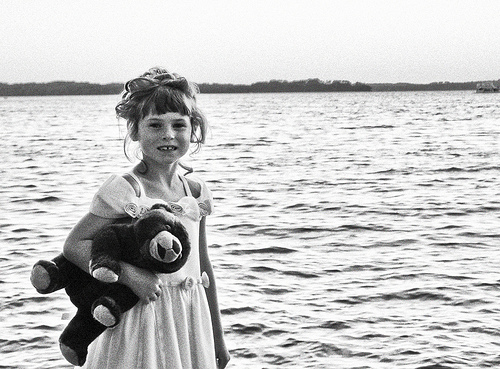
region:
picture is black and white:
[12, 23, 450, 313]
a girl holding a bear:
[16, 77, 244, 364]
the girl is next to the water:
[39, 67, 461, 362]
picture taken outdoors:
[39, 41, 462, 353]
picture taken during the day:
[9, 8, 494, 318]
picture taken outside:
[52, 54, 489, 364]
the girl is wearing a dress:
[77, 176, 224, 364]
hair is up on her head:
[105, 58, 212, 180]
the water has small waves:
[265, 93, 432, 264]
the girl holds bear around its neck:
[97, 174, 227, 357]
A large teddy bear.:
[33, 200, 201, 365]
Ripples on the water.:
[272, 255, 455, 339]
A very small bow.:
[181, 271, 218, 293]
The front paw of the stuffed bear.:
[92, 301, 115, 326]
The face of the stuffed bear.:
[133, 208, 188, 276]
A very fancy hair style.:
[110, 62, 208, 113]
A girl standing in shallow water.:
[103, 58, 233, 368]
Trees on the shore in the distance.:
[9, 75, 107, 97]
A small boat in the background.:
[473, 76, 498, 94]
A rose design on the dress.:
[120, 201, 142, 219]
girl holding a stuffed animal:
[18, 76, 259, 348]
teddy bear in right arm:
[48, 195, 208, 347]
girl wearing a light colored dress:
[114, 175, 224, 362]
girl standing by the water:
[29, 71, 476, 367]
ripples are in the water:
[272, 198, 494, 303]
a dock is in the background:
[466, 73, 498, 101]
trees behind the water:
[217, 75, 405, 105]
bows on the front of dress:
[173, 267, 221, 304]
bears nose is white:
[149, 233, 184, 275]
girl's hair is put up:
[114, 71, 217, 128]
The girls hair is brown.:
[107, 66, 209, 171]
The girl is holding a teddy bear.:
[27, 64, 229, 367]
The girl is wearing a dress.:
[28, 66, 229, 366]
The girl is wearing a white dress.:
[24, 56, 229, 367]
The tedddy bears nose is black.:
[168, 238, 183, 255]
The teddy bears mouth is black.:
[153, 241, 169, 260]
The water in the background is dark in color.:
[277, 148, 421, 245]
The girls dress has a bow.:
[182, 271, 209, 288]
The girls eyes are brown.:
[148, 118, 188, 130]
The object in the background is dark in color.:
[473, 80, 498, 92]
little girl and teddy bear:
[51, 48, 239, 366]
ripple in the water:
[314, 315, 348, 331]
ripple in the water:
[388, 342, 421, 351]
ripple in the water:
[409, 275, 434, 290]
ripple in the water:
[389, 253, 406, 265]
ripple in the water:
[447, 208, 470, 225]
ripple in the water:
[306, 249, 329, 264]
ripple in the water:
[316, 207, 337, 223]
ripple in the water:
[34, 207, 50, 219]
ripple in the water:
[393, 229, 431, 246]